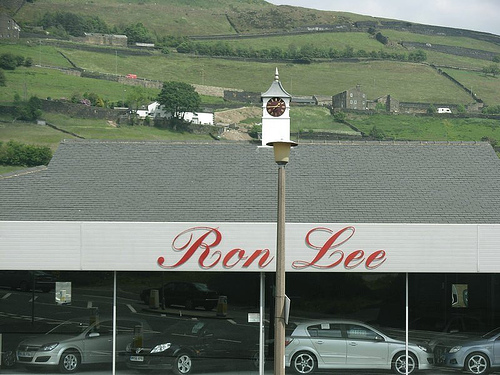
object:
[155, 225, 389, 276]
letters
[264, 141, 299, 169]
light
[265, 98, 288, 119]
clock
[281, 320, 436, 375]
car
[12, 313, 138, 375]
car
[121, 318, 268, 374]
car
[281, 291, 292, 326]
sign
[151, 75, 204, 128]
tree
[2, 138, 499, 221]
roof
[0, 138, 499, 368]
building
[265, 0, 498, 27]
sky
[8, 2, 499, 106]
hill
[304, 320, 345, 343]
window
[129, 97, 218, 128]
house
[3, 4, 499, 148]
grass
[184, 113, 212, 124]
wall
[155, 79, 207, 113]
leaves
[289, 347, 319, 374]
wheel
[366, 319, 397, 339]
windshield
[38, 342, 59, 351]
headlight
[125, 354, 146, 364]
license plate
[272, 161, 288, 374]
post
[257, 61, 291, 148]
tower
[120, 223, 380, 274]
wall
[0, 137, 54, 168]
leaves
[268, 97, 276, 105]
numbers